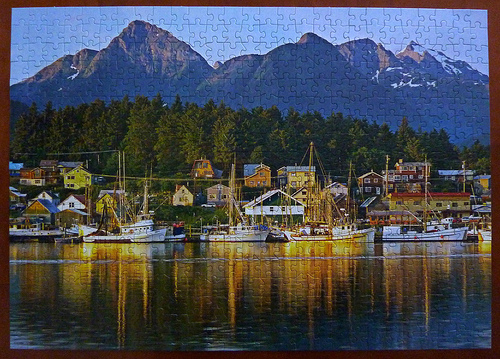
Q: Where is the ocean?
A: Across the bottom of the puzzle.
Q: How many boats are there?
A: Four.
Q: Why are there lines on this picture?
A: It's a puzzle.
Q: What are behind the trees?
A: Mountains.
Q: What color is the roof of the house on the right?
A: Blue.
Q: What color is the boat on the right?
A: White.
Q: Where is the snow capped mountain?
A: On the right.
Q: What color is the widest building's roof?
A: Red.